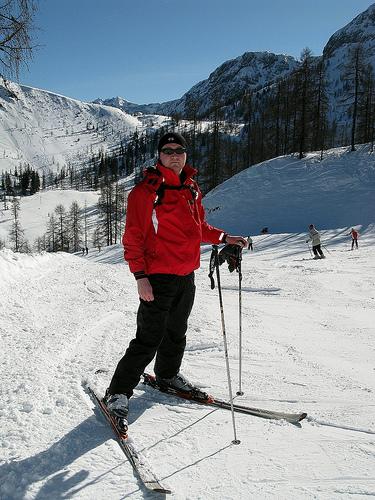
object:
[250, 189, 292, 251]
snow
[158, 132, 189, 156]
hat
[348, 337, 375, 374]
snow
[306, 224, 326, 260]
man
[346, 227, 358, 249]
man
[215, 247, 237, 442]
pole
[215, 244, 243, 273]
gloves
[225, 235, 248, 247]
hand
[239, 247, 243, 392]
pole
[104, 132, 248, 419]
man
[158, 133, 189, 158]
black cap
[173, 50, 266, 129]
mountains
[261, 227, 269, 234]
person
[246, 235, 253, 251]
people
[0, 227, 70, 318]
hill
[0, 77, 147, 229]
mountains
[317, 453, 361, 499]
snow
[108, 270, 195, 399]
pants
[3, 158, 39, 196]
trees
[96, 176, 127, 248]
trees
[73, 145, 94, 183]
trees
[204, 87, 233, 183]
trees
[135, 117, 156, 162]
trees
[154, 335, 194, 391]
boot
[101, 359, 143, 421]
boot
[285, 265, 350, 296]
snow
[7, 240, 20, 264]
ground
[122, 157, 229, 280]
coat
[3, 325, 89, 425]
snow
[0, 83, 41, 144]
snow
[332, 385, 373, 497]
ground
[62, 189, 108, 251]
trees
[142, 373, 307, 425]
ski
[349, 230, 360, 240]
jacket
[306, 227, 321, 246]
jacket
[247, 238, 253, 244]
jacket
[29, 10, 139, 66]
sky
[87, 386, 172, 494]
snow skis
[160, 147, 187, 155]
sunglasses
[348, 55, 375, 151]
tree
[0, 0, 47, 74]
branch